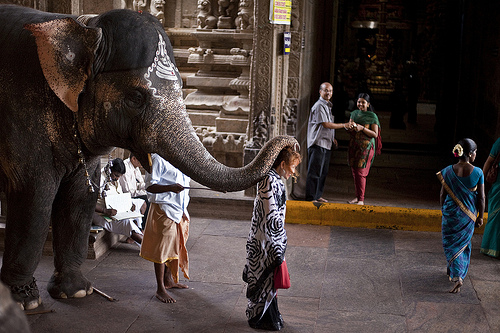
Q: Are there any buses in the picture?
A: No, there are no buses.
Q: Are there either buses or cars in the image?
A: No, there are no buses or cars.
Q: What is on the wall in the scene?
A: The sign is on the wall.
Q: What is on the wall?
A: The sign is on the wall.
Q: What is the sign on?
A: The sign is on the wall.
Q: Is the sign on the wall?
A: Yes, the sign is on the wall.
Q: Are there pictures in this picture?
A: No, there are no pictures.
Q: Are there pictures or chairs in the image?
A: No, there are no pictures or chairs.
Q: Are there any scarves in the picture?
A: Yes, there is a scarf.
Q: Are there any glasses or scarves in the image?
A: Yes, there is a scarf.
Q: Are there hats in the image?
A: No, there are no hats.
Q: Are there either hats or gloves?
A: No, there are no hats or gloves.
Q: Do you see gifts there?
A: No, there are no gifts.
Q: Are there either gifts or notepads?
A: No, there are no gifts or notepads.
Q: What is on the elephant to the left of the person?
A: The trunk is on the elephant.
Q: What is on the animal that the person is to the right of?
A: The trunk is on the elephant.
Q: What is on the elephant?
A: The trunk is on the elephant.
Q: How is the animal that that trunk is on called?
A: The animal is an elephant.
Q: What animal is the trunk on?
A: The trunk is on the elephant.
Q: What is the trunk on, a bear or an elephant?
A: The trunk is on an elephant.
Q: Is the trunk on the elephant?
A: Yes, the trunk is on the elephant.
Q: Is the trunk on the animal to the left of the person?
A: Yes, the trunk is on the elephant.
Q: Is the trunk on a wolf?
A: No, the trunk is on the elephant.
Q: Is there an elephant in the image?
A: Yes, there is an elephant.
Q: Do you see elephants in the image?
A: Yes, there is an elephant.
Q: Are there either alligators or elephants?
A: Yes, there is an elephant.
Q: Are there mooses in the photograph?
A: No, there are no mooses.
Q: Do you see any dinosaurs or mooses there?
A: No, there are no mooses or dinosaurs.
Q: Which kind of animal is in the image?
A: The animal is an elephant.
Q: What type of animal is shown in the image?
A: The animal is an elephant.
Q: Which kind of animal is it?
A: The animal is an elephant.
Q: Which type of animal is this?
A: This is an elephant.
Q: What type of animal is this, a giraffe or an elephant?
A: This is an elephant.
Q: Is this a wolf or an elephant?
A: This is an elephant.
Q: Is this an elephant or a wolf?
A: This is an elephant.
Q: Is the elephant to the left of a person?
A: Yes, the elephant is to the left of a person.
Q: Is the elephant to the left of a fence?
A: No, the elephant is to the left of a person.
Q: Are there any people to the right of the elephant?
A: Yes, there is a person to the right of the elephant.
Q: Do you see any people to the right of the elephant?
A: Yes, there is a person to the right of the elephant.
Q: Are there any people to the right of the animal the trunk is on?
A: Yes, there is a person to the right of the elephant.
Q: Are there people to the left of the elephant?
A: No, the person is to the right of the elephant.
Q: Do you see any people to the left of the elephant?
A: No, the person is to the right of the elephant.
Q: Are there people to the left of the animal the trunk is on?
A: No, the person is to the right of the elephant.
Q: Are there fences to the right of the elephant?
A: No, there is a person to the right of the elephant.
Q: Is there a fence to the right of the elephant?
A: No, there is a person to the right of the elephant.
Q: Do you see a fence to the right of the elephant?
A: No, there is a person to the right of the elephant.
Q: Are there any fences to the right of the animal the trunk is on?
A: No, there is a person to the right of the elephant.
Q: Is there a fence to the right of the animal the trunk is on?
A: No, there is a person to the right of the elephant.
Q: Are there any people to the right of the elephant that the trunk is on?
A: Yes, there is a person to the right of the elephant.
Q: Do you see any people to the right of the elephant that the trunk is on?
A: Yes, there is a person to the right of the elephant.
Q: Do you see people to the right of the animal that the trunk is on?
A: Yes, there is a person to the right of the elephant.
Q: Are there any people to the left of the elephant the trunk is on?
A: No, the person is to the right of the elephant.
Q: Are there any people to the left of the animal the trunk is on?
A: No, the person is to the right of the elephant.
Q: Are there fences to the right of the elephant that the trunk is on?
A: No, there is a person to the right of the elephant.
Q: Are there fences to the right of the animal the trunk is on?
A: No, there is a person to the right of the elephant.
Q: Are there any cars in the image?
A: No, there are no cars.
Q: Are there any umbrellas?
A: No, there are no umbrellas.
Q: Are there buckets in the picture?
A: No, there are no buckets.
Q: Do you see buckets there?
A: No, there are no buckets.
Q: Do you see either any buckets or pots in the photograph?
A: No, there are no buckets or pots.